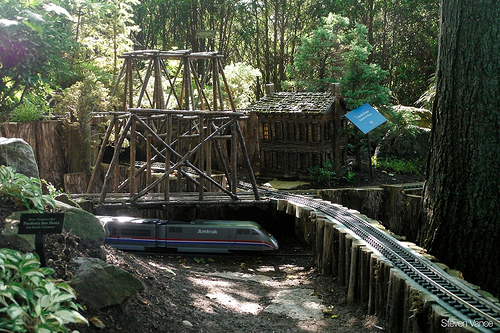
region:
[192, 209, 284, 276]
Section of a train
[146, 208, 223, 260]
Section of a train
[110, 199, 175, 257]
Section of a train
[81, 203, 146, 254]
Section of a train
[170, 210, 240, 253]
Section of a train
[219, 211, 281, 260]
Section of a train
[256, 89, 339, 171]
a wooden house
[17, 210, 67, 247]
a sign on the hill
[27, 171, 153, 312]
boulders next to the sign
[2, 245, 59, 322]
leaves on the hill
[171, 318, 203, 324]
rocks on the dirt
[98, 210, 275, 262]
a train on the tracks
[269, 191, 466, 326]
the train tracks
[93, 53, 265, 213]
a bridge over the train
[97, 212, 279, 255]
A toy train on the ground.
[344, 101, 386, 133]
A blue piece of paper.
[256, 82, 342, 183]
A little log cabin.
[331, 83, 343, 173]
A chimney to a log cabin.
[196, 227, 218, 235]
The name of the train.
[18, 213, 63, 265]
A sign with some words on it.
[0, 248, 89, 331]
A plant that is on the ground.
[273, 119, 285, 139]
A window in a cabin.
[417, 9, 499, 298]
A very tall tree.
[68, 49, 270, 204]
A toy bridge over a train.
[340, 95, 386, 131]
sign on the side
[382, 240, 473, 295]
tracks for the train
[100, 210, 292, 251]
side of the train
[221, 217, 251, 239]
the train is green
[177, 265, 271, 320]
the ground is sunny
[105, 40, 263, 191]
bridge over the track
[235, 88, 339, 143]
the house is wood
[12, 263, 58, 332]
plants on the left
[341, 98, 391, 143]
blue square sign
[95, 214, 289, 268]
silver amtrak train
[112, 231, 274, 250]
white blue and red stripe on train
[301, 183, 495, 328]
black metal train tracks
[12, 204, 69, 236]
brown sign with white letters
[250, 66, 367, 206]
small wooden brown house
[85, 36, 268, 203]
wooden tower above train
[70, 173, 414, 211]
wooden tunnel over train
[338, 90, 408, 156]
blue and white sign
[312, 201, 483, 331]
black and brown tracks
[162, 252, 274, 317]
grey rocks near train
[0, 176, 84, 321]
green plants near train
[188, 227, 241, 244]
white name on train